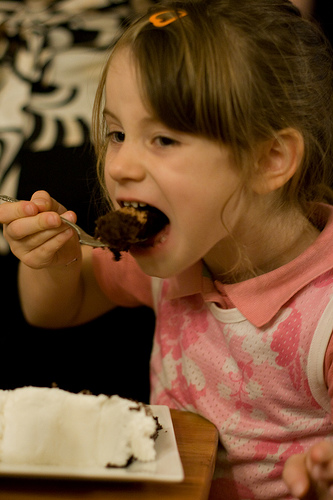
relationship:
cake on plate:
[105, 202, 170, 275] [1, 381, 192, 487]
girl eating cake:
[3, 4, 332, 494] [81, 199, 164, 265]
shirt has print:
[68, 212, 331, 498] [155, 299, 224, 386]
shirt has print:
[68, 212, 331, 498] [157, 300, 222, 378]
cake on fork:
[93, 202, 151, 247] [3, 191, 145, 254]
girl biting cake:
[3, 4, 332, 494] [96, 207, 152, 254]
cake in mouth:
[93, 202, 151, 247] [114, 197, 172, 247]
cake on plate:
[0, 383, 162, 469] [0, 402, 188, 486]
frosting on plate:
[0, 389, 159, 464] [0, 402, 188, 486]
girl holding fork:
[3, 4, 332, 494] [0, 186, 143, 249]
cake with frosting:
[0, 383, 162, 469] [0, 389, 159, 464]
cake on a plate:
[0, 383, 162, 469] [1, 381, 192, 487]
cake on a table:
[0, 383, 162, 469] [2, 388, 217, 497]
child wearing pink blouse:
[0, 0, 331, 499] [89, 198, 332, 499]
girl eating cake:
[3, 4, 332, 494] [82, 184, 171, 283]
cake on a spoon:
[93, 202, 151, 247] [1, 190, 108, 250]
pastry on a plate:
[28, 373, 159, 474] [0, 402, 188, 486]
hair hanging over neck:
[298, 173, 323, 227] [211, 220, 296, 264]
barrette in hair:
[146, 7, 194, 29] [0, 1, 331, 499]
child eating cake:
[0, 0, 331, 499] [91, 206, 160, 261]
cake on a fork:
[93, 202, 151, 247] [3, 191, 145, 254]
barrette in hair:
[146, 7, 194, 29] [89, 8, 326, 223]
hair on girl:
[89, 8, 326, 223] [3, 4, 332, 494]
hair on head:
[89, 8, 326, 223] [79, 3, 327, 281]